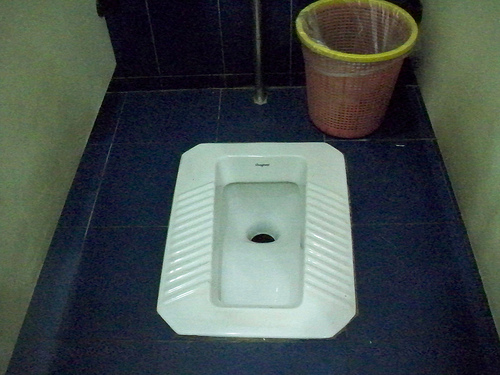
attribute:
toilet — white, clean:
[148, 139, 363, 350]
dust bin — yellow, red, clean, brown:
[290, 0, 422, 144]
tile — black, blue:
[123, 89, 219, 144]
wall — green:
[2, 1, 85, 114]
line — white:
[116, 91, 134, 105]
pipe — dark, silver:
[247, 2, 269, 105]